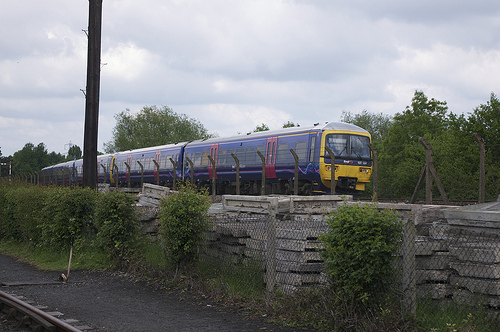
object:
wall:
[407, 176, 493, 326]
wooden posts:
[229, 152, 240, 194]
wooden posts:
[185, 157, 193, 188]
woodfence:
[364, 143, 378, 200]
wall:
[396, 200, 471, 303]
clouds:
[109, 0, 497, 85]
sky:
[2, 1, 498, 158]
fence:
[94, 206, 496, 330]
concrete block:
[273, 225, 306, 238]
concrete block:
[271, 236, 306, 251]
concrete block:
[273, 248, 305, 261]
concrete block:
[415, 252, 449, 268]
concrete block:
[302, 250, 328, 261]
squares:
[98, 181, 498, 327]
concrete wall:
[449, 260, 500, 279]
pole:
[81, 0, 102, 187]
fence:
[5, 128, 494, 207]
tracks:
[328, 193, 499, 203]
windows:
[317, 122, 374, 192]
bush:
[0, 182, 93, 251]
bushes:
[320, 203, 403, 316]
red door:
[264, 137, 276, 179]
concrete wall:
[274, 271, 321, 286]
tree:
[67, 145, 82, 160]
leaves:
[393, 89, 455, 149]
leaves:
[462, 90, 499, 167]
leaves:
[349, 113, 387, 132]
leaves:
[112, 106, 209, 151]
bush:
[157, 181, 209, 277]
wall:
[224, 196, 288, 299]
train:
[98, 121, 381, 198]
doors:
[208, 144, 217, 180]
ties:
[0, 287, 85, 332]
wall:
[93, 181, 499, 326]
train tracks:
[353, 197, 494, 205]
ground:
[2, 242, 316, 328]